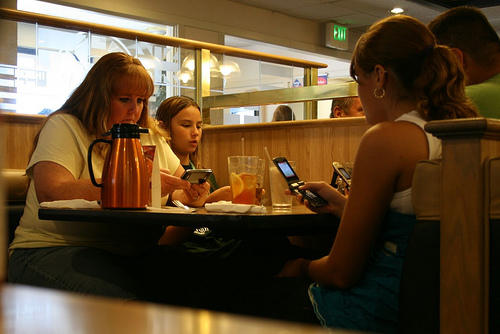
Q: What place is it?
A: It is a restaurant.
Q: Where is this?
A: This is at the restaurant.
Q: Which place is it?
A: It is a restaurant.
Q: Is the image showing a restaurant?
A: Yes, it is showing a restaurant.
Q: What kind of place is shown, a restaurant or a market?
A: It is a restaurant.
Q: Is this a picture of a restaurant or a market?
A: It is showing a restaurant.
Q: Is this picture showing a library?
A: No, the picture is showing a restaurant.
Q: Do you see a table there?
A: Yes, there is a table.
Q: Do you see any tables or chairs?
A: Yes, there is a table.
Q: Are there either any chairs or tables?
A: Yes, there is a table.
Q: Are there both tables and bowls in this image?
A: No, there is a table but no bowls.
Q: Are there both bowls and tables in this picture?
A: No, there is a table but no bowls.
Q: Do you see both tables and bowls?
A: No, there is a table but no bowls.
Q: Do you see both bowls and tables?
A: No, there is a table but no bowls.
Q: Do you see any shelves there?
A: No, there are no shelves.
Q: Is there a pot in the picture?
A: Yes, there is a pot.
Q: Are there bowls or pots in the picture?
A: Yes, there is a pot.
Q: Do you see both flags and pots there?
A: No, there is a pot but no flags.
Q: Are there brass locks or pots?
A: Yes, there is a brass pot.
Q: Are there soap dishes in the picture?
A: No, there are no soap dishes.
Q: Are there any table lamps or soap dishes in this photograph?
A: No, there are no soap dishes or table lamps.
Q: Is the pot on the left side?
A: Yes, the pot is on the left of the image.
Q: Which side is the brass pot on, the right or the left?
A: The pot is on the left of the image.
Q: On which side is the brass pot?
A: The pot is on the left of the image.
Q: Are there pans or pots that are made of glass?
A: No, there is a pot but it is made of brass.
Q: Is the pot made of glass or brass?
A: The pot is made of brass.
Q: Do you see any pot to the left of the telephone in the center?
A: Yes, there is a pot to the left of the phone.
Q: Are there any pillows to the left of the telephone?
A: No, there is a pot to the left of the telephone.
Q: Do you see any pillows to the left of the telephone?
A: No, there is a pot to the left of the telephone.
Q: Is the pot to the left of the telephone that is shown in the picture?
A: Yes, the pot is to the left of the telephone.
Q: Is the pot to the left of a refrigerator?
A: No, the pot is to the left of the telephone.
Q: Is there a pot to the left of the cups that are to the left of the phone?
A: Yes, there is a pot to the left of the cups.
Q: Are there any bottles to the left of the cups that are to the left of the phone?
A: No, there is a pot to the left of the cups.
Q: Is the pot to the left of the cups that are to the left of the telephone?
A: Yes, the pot is to the left of the cups.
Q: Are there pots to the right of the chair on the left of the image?
A: Yes, there is a pot to the right of the chair.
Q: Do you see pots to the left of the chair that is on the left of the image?
A: No, the pot is to the right of the chair.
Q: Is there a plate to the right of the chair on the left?
A: No, there is a pot to the right of the chair.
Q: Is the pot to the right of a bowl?
A: No, the pot is to the right of a chair.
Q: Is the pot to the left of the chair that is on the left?
A: No, the pot is to the right of the chair.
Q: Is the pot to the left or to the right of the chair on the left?
A: The pot is to the right of the chair.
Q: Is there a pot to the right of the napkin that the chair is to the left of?
A: Yes, there is a pot to the right of the napkin.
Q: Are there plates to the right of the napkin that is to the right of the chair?
A: No, there is a pot to the right of the napkin.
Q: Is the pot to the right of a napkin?
A: Yes, the pot is to the right of a napkin.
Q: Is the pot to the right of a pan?
A: No, the pot is to the right of a napkin.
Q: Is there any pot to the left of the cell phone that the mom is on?
A: Yes, there is a pot to the left of the cell phone.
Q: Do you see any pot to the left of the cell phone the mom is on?
A: Yes, there is a pot to the left of the cell phone.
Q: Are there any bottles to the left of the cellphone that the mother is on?
A: No, there is a pot to the left of the mobile phone.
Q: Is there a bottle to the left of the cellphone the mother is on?
A: No, there is a pot to the left of the mobile phone.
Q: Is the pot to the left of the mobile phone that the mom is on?
A: Yes, the pot is to the left of the cell phone.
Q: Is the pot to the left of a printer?
A: No, the pot is to the left of the cell phone.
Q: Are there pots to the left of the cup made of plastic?
A: Yes, there is a pot to the left of the cup.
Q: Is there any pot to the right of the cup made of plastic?
A: No, the pot is to the left of the cup.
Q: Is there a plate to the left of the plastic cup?
A: No, there is a pot to the left of the cup.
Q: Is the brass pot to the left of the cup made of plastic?
A: Yes, the pot is to the left of the cup.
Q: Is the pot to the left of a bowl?
A: No, the pot is to the left of the cup.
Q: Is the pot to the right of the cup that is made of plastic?
A: No, the pot is to the left of the cup.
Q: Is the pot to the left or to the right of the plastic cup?
A: The pot is to the left of the cup.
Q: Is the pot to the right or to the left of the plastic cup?
A: The pot is to the left of the cup.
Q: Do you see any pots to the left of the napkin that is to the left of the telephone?
A: Yes, there is a pot to the left of the napkin.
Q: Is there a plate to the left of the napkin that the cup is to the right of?
A: No, there is a pot to the left of the napkin.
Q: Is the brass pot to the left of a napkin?
A: Yes, the pot is to the left of a napkin.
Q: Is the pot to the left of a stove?
A: No, the pot is to the left of a napkin.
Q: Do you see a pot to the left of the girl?
A: Yes, there is a pot to the left of the girl.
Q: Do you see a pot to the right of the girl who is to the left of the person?
A: No, the pot is to the left of the girl.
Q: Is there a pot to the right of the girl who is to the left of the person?
A: No, the pot is to the left of the girl.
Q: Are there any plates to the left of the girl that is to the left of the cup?
A: No, there is a pot to the left of the girl.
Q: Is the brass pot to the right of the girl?
A: No, the pot is to the left of the girl.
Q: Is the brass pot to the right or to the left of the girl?
A: The pot is to the left of the girl.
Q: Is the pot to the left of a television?
A: No, the pot is to the left of a cell phone.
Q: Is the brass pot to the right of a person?
A: No, the pot is to the left of a person.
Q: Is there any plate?
A: No, there are no plates.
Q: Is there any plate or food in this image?
A: No, there are no plates or food.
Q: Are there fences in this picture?
A: No, there are no fences.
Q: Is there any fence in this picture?
A: No, there are no fences.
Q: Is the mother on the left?
A: Yes, the mother is on the left of the image.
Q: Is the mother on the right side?
A: No, the mother is on the left of the image.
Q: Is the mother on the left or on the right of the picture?
A: The mother is on the left of the image.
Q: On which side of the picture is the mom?
A: The mom is on the left of the image.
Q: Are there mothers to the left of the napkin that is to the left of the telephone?
A: Yes, there is a mother to the left of the napkin.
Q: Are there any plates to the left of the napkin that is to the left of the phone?
A: No, there is a mother to the left of the napkin.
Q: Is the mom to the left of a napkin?
A: Yes, the mom is to the left of a napkin.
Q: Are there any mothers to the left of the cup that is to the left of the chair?
A: Yes, there is a mother to the left of the cup.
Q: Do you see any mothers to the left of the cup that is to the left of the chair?
A: Yes, there is a mother to the left of the cup.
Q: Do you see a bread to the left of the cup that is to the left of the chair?
A: No, there is a mother to the left of the cup.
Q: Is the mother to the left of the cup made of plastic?
A: Yes, the mother is to the left of the cup.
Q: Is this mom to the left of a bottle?
A: No, the mom is to the left of the cup.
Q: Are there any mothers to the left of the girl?
A: Yes, there is a mother to the left of the girl.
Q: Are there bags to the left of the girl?
A: No, there is a mother to the left of the girl.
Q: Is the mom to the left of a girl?
A: Yes, the mom is to the left of a girl.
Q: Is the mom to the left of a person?
A: Yes, the mom is to the left of a person.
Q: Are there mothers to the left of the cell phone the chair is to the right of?
A: Yes, there is a mother to the left of the mobile phone.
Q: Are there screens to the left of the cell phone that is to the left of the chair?
A: No, there is a mother to the left of the mobile phone.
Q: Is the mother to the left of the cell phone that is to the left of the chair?
A: Yes, the mother is to the left of the cell phone.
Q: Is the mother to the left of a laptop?
A: No, the mother is to the left of the cell phone.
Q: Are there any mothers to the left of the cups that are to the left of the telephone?
A: Yes, there is a mother to the left of the cups.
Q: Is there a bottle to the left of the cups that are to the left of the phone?
A: No, there is a mother to the left of the cups.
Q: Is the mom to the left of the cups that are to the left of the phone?
A: Yes, the mom is to the left of the cups.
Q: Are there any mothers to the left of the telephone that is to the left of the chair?
A: Yes, there is a mother to the left of the phone.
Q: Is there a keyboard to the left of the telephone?
A: No, there is a mother to the left of the telephone.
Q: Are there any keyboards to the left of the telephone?
A: No, there is a mother to the left of the telephone.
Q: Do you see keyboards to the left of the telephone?
A: No, there is a mother to the left of the telephone.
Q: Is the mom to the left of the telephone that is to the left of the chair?
A: Yes, the mom is to the left of the telephone.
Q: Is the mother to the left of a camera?
A: No, the mother is to the left of the telephone.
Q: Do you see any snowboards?
A: No, there are no snowboards.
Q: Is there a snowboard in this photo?
A: No, there are no snowboards.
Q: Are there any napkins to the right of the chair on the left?
A: Yes, there is a napkin to the right of the chair.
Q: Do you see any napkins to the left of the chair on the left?
A: No, the napkin is to the right of the chair.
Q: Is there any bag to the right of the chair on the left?
A: No, there is a napkin to the right of the chair.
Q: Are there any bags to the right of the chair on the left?
A: No, there is a napkin to the right of the chair.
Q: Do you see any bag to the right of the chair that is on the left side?
A: No, there is a napkin to the right of the chair.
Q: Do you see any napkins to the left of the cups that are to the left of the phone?
A: Yes, there is a napkin to the left of the cups.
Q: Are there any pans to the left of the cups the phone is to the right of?
A: No, there is a napkin to the left of the cups.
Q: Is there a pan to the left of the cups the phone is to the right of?
A: No, there is a napkin to the left of the cups.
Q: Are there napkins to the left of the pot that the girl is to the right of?
A: Yes, there is a napkin to the left of the pot.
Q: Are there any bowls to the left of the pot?
A: No, there is a napkin to the left of the pot.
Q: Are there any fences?
A: No, there are no fences.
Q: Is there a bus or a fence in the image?
A: No, there are no fences or buses.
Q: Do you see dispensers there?
A: No, there are no dispensers.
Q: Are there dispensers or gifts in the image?
A: No, there are no dispensers or gifts.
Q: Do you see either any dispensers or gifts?
A: No, there are no dispensers or gifts.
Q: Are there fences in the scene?
A: No, there are no fences.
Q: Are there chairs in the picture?
A: Yes, there is a chair.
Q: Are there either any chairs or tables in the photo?
A: Yes, there is a chair.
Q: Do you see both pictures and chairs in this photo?
A: No, there is a chair but no pictures.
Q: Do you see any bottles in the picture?
A: No, there are no bottles.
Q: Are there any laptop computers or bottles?
A: No, there are no bottles or laptop computers.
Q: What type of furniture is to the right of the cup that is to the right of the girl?
A: The piece of furniture is a chair.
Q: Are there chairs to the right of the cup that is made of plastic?
A: Yes, there is a chair to the right of the cup.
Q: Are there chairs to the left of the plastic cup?
A: No, the chair is to the right of the cup.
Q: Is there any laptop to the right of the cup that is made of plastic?
A: No, there is a chair to the right of the cup.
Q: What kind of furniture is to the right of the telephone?
A: The piece of furniture is a chair.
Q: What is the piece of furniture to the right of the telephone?
A: The piece of furniture is a chair.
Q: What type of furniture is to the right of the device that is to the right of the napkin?
A: The piece of furniture is a chair.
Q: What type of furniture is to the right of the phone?
A: The piece of furniture is a chair.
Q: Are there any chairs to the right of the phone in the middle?
A: Yes, there is a chair to the right of the telephone.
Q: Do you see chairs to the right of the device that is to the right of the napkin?
A: Yes, there is a chair to the right of the telephone.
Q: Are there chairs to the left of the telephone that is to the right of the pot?
A: No, the chair is to the right of the telephone.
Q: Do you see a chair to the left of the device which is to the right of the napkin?
A: No, the chair is to the right of the telephone.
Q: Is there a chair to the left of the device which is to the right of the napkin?
A: No, the chair is to the right of the telephone.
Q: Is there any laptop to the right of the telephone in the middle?
A: No, there is a chair to the right of the phone.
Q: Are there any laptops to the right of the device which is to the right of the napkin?
A: No, there is a chair to the right of the phone.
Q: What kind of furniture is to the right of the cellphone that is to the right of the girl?
A: The piece of furniture is a chair.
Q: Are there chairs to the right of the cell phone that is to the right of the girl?
A: Yes, there is a chair to the right of the cell phone.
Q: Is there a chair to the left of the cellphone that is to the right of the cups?
A: No, the chair is to the right of the cellphone.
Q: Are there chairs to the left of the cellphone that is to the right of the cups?
A: No, the chair is to the right of the cellphone.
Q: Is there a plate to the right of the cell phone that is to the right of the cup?
A: No, there is a chair to the right of the cellphone.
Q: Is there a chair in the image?
A: Yes, there is a chair.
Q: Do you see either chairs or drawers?
A: Yes, there is a chair.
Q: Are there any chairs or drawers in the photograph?
A: Yes, there is a chair.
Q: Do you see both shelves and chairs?
A: No, there is a chair but no shelves.